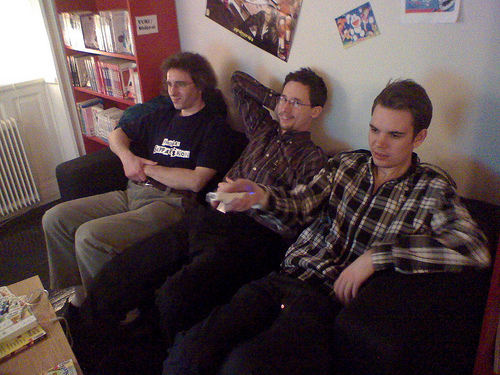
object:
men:
[162, 76, 493, 375]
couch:
[55, 133, 498, 375]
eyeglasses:
[277, 96, 312, 109]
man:
[80, 67, 330, 375]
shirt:
[252, 148, 492, 296]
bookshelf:
[51, 0, 179, 157]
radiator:
[0, 118, 42, 218]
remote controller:
[206, 192, 247, 214]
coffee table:
[0, 274, 84, 375]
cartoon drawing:
[333, 1, 382, 49]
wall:
[174, 0, 500, 211]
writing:
[153, 138, 191, 159]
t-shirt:
[113, 103, 230, 192]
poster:
[202, 0, 302, 63]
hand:
[211, 176, 265, 214]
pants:
[161, 274, 345, 375]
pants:
[41, 178, 198, 308]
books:
[60, 12, 133, 57]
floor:
[0, 193, 68, 288]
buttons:
[252, 167, 256, 171]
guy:
[40, 52, 234, 305]